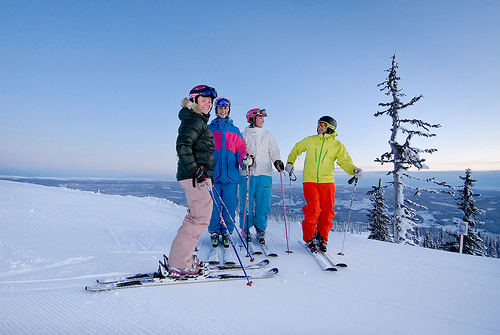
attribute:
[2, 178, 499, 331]
snow — white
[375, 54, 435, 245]
tree — bare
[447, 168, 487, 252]
tree — green, bare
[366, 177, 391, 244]
tree — green, bare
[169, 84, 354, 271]
group — skiing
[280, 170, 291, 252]
ski-pole — pink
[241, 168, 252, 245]
ski-pole — pink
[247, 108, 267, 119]
helmet — pink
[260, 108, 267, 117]
goggles — blue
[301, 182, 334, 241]
pants — red, orange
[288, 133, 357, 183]
jacket — yellow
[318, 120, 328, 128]
goggles — orange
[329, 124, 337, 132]
straps — yellow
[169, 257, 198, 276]
boots — pink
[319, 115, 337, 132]
helmet — black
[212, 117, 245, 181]
jacket — muli-colored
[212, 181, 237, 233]
pants — blue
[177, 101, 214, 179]
jacket — black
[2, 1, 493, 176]
sky — blue, clear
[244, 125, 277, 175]
jacket — white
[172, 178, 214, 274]
pants — pink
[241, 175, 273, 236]
pants — blue